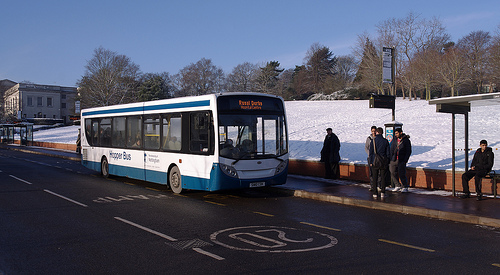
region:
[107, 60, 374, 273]
a bus on the road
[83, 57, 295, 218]
a bus on the street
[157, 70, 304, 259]
a road iwth abus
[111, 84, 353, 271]
a street with a bus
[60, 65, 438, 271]
a passenger bus on the road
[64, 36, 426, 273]
a passenger bus on the street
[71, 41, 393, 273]
a road with a passenger bus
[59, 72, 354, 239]
a street with a passenger bus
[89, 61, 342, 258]
a bus that is blue and white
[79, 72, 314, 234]
a white and blue bus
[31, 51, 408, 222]
a bus in the road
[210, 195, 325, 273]
a number on the road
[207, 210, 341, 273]
a circle in the road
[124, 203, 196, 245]
white lines in the road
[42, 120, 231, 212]
tires of the bus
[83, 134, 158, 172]
name of the bus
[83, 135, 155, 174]
name on the bus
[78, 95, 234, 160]
windows on the side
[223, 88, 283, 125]
display on the top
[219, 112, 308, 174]
front glass on the bus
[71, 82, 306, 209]
A public bus ready to pick up passengers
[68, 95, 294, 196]
bus on a street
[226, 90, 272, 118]
sign on a bus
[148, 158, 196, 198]
tire on a bus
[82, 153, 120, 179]
tire on a bus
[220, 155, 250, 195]
light on a bus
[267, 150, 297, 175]
light on a bus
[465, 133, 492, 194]
man wearing a black jacket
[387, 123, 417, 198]
man wearing a jacket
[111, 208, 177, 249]
line on a street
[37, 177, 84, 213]
line on a street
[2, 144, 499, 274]
The street beneath the bus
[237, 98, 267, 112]
An electronic display on the bus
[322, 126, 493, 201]
People standing near the bus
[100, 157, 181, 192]
Wheels on the bus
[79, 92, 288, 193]
A bus by the side of the road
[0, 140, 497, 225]
The sidewalk by the street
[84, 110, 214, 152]
Windows on the bus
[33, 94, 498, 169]
Snow near the sidewalk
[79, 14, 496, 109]
Trees on the snow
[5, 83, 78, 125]
A building behind the bus